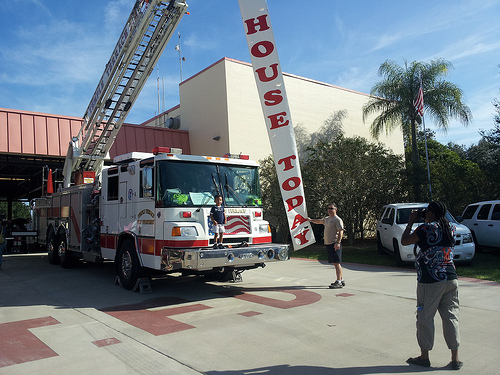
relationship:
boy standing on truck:
[210, 192, 227, 246] [37, 153, 278, 286]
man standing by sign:
[320, 197, 349, 288] [243, 5, 315, 251]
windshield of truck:
[157, 159, 261, 205] [37, 153, 278, 286]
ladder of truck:
[62, 0, 191, 173] [37, 153, 278, 286]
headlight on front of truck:
[175, 225, 197, 237] [37, 153, 278, 286]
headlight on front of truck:
[257, 225, 273, 233] [37, 153, 278, 286]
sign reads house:
[243, 5, 315, 251] [247, 14, 289, 131]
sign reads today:
[243, 5, 315, 251] [283, 152, 314, 243]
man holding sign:
[320, 197, 349, 288] [243, 5, 315, 251]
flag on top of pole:
[414, 79, 428, 115] [420, 77, 432, 203]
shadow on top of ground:
[206, 360, 436, 373] [17, 257, 487, 371]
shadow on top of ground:
[225, 278, 336, 302] [17, 257, 487, 371]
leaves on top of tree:
[364, 59, 463, 124] [365, 61, 468, 201]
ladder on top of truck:
[62, 0, 191, 173] [37, 153, 278, 286]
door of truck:
[135, 168, 158, 243] [37, 153, 278, 286]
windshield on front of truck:
[157, 159, 261, 205] [37, 153, 278, 286]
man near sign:
[320, 197, 349, 288] [243, 5, 315, 251]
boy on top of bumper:
[210, 192, 227, 246] [177, 242, 287, 268]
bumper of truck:
[177, 242, 287, 268] [37, 153, 278, 286]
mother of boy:
[414, 203, 464, 363] [210, 192, 227, 246]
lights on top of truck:
[152, 141, 186, 154] [37, 153, 278, 286]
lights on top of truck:
[223, 151, 249, 162] [37, 153, 278, 286]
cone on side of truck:
[44, 167, 58, 193] [37, 153, 278, 286]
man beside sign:
[320, 197, 349, 288] [243, 5, 315, 251]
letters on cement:
[1, 284, 320, 361] [17, 257, 487, 371]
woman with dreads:
[414, 203, 464, 363] [432, 200, 454, 242]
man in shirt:
[320, 197, 349, 288] [321, 211, 347, 244]